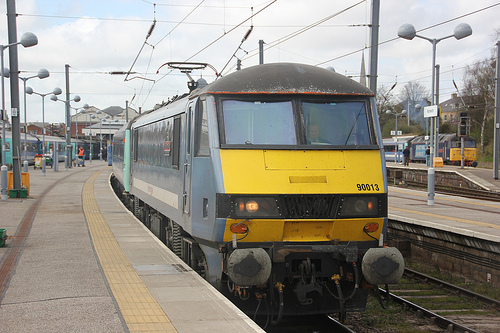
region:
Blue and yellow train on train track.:
[140, 53, 420, 298]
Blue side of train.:
[1, 130, 91, 166]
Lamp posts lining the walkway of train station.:
[6, 27, 101, 192]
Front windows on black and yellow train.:
[215, 91, 382, 151]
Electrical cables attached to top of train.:
[120, 15, 315, 80]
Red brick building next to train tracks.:
[440, 90, 490, 125]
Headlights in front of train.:
[236, 191, 382, 218]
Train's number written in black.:
[351, 177, 384, 193]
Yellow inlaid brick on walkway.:
[75, 193, 176, 332]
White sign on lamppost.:
[417, 102, 445, 122]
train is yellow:
[108, 62, 408, 323]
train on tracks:
[105, 58, 411, 326]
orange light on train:
[234, 194, 247, 223]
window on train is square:
[210, 87, 380, 154]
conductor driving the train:
[303, 117, 333, 142]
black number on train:
[353, 176, 380, 193]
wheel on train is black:
[161, 213, 182, 258]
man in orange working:
[71, 141, 87, 168]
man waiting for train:
[397, 141, 412, 169]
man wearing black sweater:
[402, 139, 414, 166]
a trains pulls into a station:
[29, 9, 490, 327]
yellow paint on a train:
[212, 143, 407, 248]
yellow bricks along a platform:
[84, 176, 119, 303]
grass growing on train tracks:
[431, 286, 453, 313]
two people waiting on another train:
[386, 134, 496, 166]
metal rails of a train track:
[399, 296, 446, 321]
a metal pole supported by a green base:
[4, 9, 28, 200]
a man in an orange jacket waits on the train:
[77, 143, 97, 165]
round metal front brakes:
[223, 242, 422, 287]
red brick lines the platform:
[14, 205, 31, 240]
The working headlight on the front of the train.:
[235, 196, 272, 215]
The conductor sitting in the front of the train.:
[306, 111, 329, 145]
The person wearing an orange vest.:
[73, 143, 87, 161]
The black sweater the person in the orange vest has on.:
[74, 146, 86, 157]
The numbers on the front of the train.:
[354, 180, 381, 193]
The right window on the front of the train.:
[299, 100, 377, 145]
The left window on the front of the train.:
[218, 98, 298, 143]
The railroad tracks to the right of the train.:
[393, 289, 498, 321]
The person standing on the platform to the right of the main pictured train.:
[403, 146, 410, 168]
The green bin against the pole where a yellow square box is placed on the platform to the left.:
[6, 180, 28, 198]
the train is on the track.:
[103, 102, 398, 309]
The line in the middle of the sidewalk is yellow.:
[61, 170, 161, 331]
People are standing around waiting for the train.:
[34, 136, 113, 173]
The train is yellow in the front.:
[202, 143, 406, 226]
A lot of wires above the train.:
[127, 19, 382, 74]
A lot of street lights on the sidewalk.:
[13, 49, 84, 113]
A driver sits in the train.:
[303, 112, 386, 163]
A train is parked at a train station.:
[68, 64, 442, 279]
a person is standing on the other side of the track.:
[401, 126, 424, 178]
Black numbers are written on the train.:
[344, 179, 384, 200]